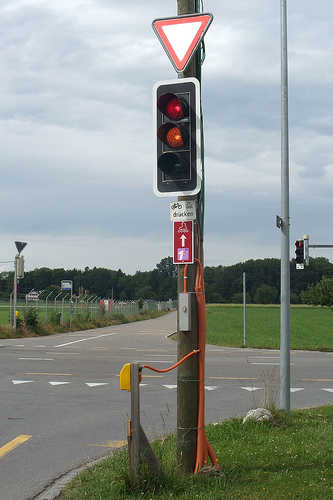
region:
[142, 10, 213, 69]
street sign on the pole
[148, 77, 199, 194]
traffic signal attached to the pole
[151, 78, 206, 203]
traffic signal on the pole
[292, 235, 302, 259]
traffic signal on the pole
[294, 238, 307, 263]
traffic signal attached to the pole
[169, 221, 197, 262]
sign attached to the pole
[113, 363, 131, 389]
electric box on the pole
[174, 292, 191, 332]
electric box on the pole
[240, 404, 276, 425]
rock next to the pole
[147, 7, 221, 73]
Triangle shaped sign on pole.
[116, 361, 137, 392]
Yellow box on the pole.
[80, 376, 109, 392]
White triangle on the road.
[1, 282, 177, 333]
Fence in the background.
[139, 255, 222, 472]
Orange cable on poles.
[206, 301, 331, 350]
Green grass covering the ground.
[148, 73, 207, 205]
Traffic signal on the pole.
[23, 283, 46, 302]
House in the background.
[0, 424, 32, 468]
Yellow line on the road.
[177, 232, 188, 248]
White arrow on the sign.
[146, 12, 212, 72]
a red and white triangular sign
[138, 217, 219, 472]
an orange electrical cord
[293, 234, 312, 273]
a stop light on red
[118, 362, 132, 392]
a yellow electrical box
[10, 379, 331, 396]
white triangles painted on the road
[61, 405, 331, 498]
a green grassy area by the road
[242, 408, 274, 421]
a white rock beside the road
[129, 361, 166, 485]
a wooden post for the electrical box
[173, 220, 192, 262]
a red and white sign with an arrow pointing up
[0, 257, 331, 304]
tall trees in the background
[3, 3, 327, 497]
a scene outside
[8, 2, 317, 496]
a scene during the day time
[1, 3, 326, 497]
a scene at a street corner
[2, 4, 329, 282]
a sky with clouds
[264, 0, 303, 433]
a gray pole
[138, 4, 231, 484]
a traffic light on red and orange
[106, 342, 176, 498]
an electrical outlet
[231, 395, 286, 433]
a gray rock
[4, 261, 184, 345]
a fence in the background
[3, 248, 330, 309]
a row of trees in the distance